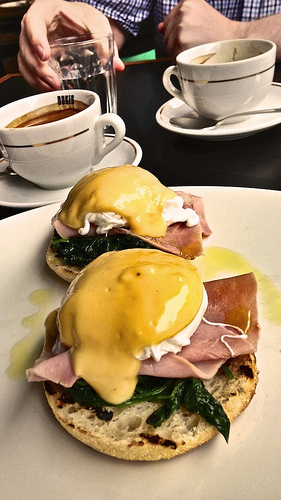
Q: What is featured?
A: Food.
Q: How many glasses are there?
A: One.